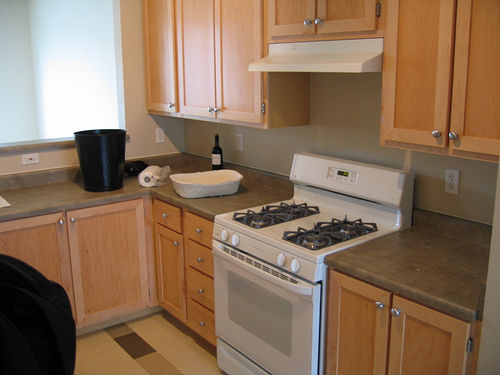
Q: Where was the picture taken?
A: It was taken at the kitchen.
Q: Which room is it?
A: It is a kitchen.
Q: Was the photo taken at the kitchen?
A: Yes, it was taken in the kitchen.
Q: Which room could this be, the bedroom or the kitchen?
A: It is the kitchen.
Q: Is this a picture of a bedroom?
A: No, the picture is showing a kitchen.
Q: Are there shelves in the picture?
A: No, there are no shelves.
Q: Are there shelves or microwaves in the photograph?
A: No, there are no shelves or microwaves.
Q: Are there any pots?
A: No, there are no pots.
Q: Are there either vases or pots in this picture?
A: No, there are no pots or vases.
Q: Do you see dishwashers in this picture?
A: No, there are no dishwashers.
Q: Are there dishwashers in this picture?
A: No, there are no dishwashers.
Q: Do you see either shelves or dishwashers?
A: No, there are no dishwashers or shelves.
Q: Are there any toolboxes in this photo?
A: No, there are no toolboxes.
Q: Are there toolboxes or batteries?
A: No, there are no toolboxes or batteries.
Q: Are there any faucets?
A: No, there are no faucets.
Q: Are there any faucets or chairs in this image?
A: No, there are no faucets or chairs.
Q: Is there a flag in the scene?
A: No, there are no flags.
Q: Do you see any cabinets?
A: Yes, there is a cabinet.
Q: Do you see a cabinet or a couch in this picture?
A: Yes, there is a cabinet.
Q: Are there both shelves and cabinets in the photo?
A: No, there is a cabinet but no shelves.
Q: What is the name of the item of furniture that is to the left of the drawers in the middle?
A: The piece of furniture is a cabinet.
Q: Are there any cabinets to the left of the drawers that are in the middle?
A: Yes, there is a cabinet to the left of the drawers.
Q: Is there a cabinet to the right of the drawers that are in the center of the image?
A: No, the cabinet is to the left of the drawers.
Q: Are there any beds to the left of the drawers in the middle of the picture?
A: No, there is a cabinet to the left of the drawers.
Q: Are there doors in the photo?
A: Yes, there is a door.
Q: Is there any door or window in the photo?
A: Yes, there is a door.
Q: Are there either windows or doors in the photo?
A: Yes, there is a door.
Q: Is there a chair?
A: No, there are no chairs.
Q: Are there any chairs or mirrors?
A: No, there are no chairs or mirrors.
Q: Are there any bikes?
A: No, there are no bikes.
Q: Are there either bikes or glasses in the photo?
A: No, there are no bikes or glasses.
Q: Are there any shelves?
A: No, there are no shelves.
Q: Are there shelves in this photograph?
A: No, there are no shelves.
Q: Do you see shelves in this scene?
A: No, there are no shelves.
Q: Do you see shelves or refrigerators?
A: No, there are no shelves or refrigerators.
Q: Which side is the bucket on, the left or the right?
A: The bucket is on the left of the image.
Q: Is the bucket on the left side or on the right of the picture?
A: The bucket is on the left of the image.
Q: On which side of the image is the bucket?
A: The bucket is on the left of the image.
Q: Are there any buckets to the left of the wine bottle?
A: Yes, there is a bucket to the left of the wine bottle.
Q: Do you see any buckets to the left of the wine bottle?
A: Yes, there is a bucket to the left of the wine bottle.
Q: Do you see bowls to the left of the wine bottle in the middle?
A: No, there is a bucket to the left of the wine bottle.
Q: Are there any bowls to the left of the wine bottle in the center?
A: No, there is a bucket to the left of the wine bottle.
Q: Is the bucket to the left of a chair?
A: No, the bucket is to the left of a wine bottle.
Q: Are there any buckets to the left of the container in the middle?
A: Yes, there is a bucket to the left of the container.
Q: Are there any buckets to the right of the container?
A: No, the bucket is to the left of the container.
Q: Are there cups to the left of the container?
A: No, there is a bucket to the left of the container.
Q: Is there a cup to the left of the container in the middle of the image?
A: No, there is a bucket to the left of the container.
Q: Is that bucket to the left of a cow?
A: No, the bucket is to the left of the container.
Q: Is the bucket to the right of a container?
A: No, the bucket is to the left of a container.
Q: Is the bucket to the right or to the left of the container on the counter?
A: The bucket is to the left of the container.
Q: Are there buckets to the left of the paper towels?
A: Yes, there is a bucket to the left of the paper towels.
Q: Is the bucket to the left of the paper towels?
A: Yes, the bucket is to the left of the paper towels.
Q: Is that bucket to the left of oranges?
A: No, the bucket is to the left of the paper towels.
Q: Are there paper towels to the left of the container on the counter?
A: Yes, there are paper towels to the left of the container.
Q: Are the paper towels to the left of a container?
A: Yes, the paper towels are to the left of a container.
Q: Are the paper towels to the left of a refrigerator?
A: No, the paper towels are to the left of a container.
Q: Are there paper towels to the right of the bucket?
A: Yes, there are paper towels to the right of the bucket.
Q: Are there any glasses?
A: No, there are no glasses.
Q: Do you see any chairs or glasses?
A: No, there are no glasses or chairs.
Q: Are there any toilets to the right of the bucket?
A: No, there is a wine bottle to the right of the bucket.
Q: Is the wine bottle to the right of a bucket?
A: Yes, the wine bottle is to the right of a bucket.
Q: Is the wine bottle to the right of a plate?
A: No, the wine bottle is to the right of a bucket.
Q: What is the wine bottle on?
A: The wine bottle is on the counter.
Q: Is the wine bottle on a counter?
A: Yes, the wine bottle is on a counter.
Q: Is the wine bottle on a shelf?
A: No, the wine bottle is on a counter.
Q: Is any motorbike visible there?
A: No, there are no motorcycles.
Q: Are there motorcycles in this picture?
A: No, there are no motorcycles.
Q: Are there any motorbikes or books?
A: No, there are no motorbikes or books.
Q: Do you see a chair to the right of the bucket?
A: No, there is a container to the right of the bucket.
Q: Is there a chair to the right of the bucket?
A: No, there is a container to the right of the bucket.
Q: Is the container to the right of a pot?
A: No, the container is to the right of the bucket.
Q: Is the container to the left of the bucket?
A: No, the container is to the right of the bucket.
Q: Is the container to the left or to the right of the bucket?
A: The container is to the right of the bucket.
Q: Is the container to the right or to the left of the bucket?
A: The container is to the right of the bucket.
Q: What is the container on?
A: The container is on the counter.